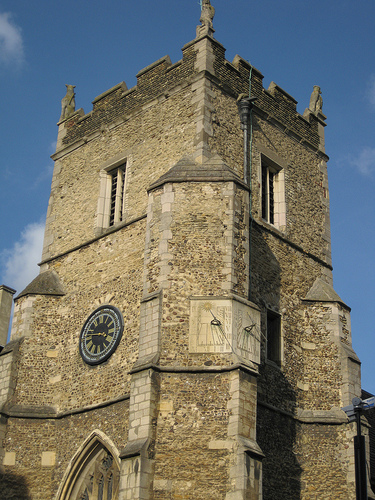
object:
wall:
[35, 91, 204, 497]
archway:
[56, 428, 122, 500]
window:
[95, 156, 127, 239]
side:
[201, 52, 330, 436]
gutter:
[242, 62, 258, 197]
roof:
[11, 268, 63, 304]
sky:
[2, 1, 373, 264]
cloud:
[2, 8, 30, 76]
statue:
[60, 80, 75, 120]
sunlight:
[2, 0, 362, 111]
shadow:
[259, 363, 304, 496]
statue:
[192, 0, 216, 43]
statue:
[309, 84, 324, 114]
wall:
[146, 180, 326, 499]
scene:
[188, 290, 264, 364]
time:
[82, 331, 114, 342]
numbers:
[98, 314, 104, 324]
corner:
[125, 168, 255, 500]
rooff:
[53, 4, 327, 146]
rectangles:
[96, 156, 128, 235]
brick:
[154, 112, 175, 127]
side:
[28, 72, 190, 499]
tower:
[7, 0, 353, 492]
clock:
[78, 306, 124, 363]